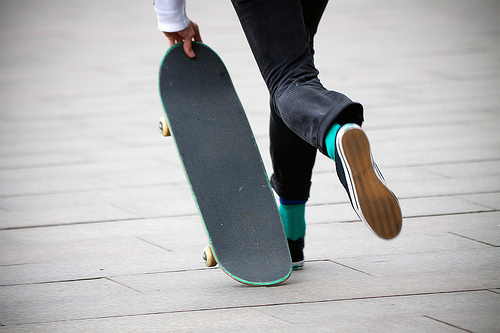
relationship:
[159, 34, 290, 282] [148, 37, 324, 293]
top on skateboard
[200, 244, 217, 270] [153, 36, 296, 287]
wheel on skateboard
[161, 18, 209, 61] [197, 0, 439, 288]
hand on person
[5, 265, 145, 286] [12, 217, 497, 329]
crack on brick ground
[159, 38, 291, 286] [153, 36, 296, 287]
rim around skateboard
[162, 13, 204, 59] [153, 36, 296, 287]
hand holding skateboard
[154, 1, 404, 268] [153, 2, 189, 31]
person has shirt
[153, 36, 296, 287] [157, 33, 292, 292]
skateboard with trim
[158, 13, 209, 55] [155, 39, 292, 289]
hand holding board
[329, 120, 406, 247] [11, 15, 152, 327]
foot on ground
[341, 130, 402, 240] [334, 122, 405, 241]
sole of sneaker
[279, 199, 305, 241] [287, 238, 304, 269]
sock in sneaker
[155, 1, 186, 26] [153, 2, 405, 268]
wrist of skateboarder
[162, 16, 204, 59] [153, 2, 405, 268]
left hand of skateboarder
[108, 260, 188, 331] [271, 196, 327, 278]
cement with foot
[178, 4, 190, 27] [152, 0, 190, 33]
seam in cuff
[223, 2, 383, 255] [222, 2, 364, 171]
legs with pants